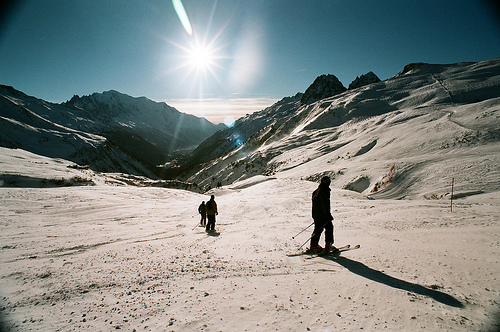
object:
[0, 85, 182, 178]
mountains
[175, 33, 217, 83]
sun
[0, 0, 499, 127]
sky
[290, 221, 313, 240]
left ski pole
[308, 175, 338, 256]
skier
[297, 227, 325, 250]
right ski pole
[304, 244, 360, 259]
skis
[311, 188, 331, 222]
jacket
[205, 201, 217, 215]
jacket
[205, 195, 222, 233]
skier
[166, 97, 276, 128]
clouds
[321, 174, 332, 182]
hat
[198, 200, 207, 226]
person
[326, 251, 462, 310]
shadow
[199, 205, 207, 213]
coat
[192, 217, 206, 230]
pole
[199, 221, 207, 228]
skis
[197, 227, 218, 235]
skis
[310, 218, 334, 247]
pants